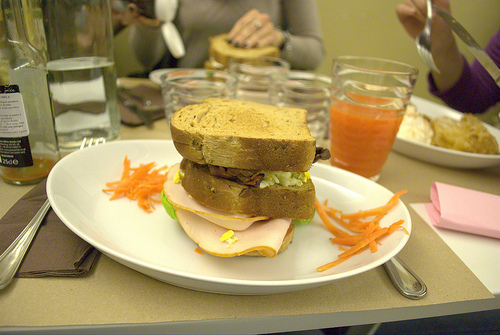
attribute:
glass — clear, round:
[330, 54, 420, 181]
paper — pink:
[423, 181, 498, 238]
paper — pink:
[426, 177, 499, 239]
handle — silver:
[382, 254, 427, 300]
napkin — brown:
[8, 169, 98, 301]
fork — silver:
[6, 189, 58, 306]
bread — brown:
[161, 94, 318, 222]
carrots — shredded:
[319, 192, 403, 262]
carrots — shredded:
[99, 148, 171, 215]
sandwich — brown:
[169, 94, 314, 223]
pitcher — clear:
[35, 3, 127, 155]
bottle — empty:
[5, 22, 105, 202]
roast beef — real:
[202, 165, 262, 185]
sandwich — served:
[163, 90, 325, 247]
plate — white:
[46, 138, 411, 295]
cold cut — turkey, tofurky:
[159, 95, 315, 258]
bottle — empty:
[3, 18, 60, 188]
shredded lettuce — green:
[261, 170, 306, 188]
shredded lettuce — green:
[161, 190, 176, 220]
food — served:
[410, 115, 495, 150]